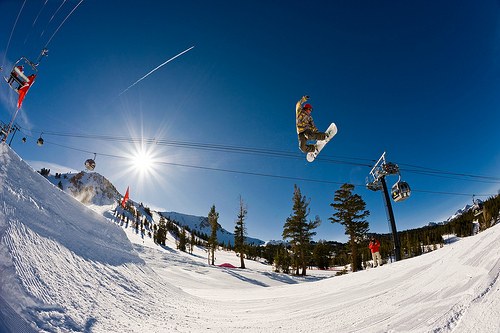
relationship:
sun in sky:
[111, 125, 167, 186] [197, 78, 255, 120]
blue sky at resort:
[29, 1, 499, 94] [70, 171, 498, 299]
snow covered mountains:
[0, 141, 500, 333] [157, 200, 299, 271]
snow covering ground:
[0, 141, 500, 333] [147, 281, 272, 328]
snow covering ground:
[12, 287, 498, 331] [12, 270, 496, 331]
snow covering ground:
[0, 141, 500, 333] [44, 274, 215, 323]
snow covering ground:
[0, 141, 500, 333] [379, 282, 447, 329]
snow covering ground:
[0, 141, 500, 333] [0, 261, 483, 329]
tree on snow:
[270, 182, 322, 276] [0, 141, 500, 333]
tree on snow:
[332, 176, 376, 274] [0, 141, 500, 333]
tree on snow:
[230, 187, 255, 274] [0, 141, 500, 333]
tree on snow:
[195, 200, 226, 268] [0, 141, 500, 333]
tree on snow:
[175, 222, 187, 256] [0, 141, 500, 333]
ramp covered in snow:
[9, 143, 231, 330] [27, 273, 484, 331]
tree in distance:
[279, 180, 322, 278] [6, 5, 493, 245]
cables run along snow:
[1, 119, 498, 197] [1, 253, 498, 331]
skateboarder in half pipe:
[289, 90, 339, 165] [3, 139, 496, 330]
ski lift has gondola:
[0, 122, 496, 205] [387, 165, 414, 203]